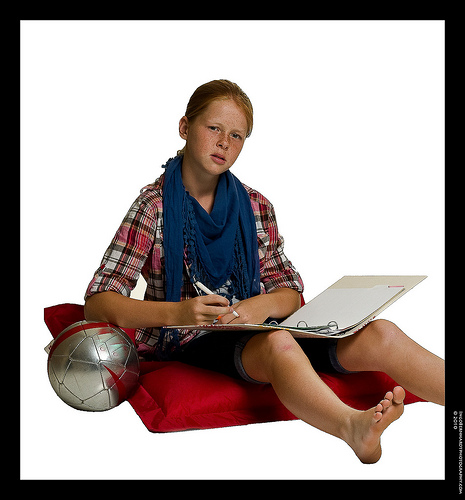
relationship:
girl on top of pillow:
[84, 79, 444, 462] [43, 302, 428, 431]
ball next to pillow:
[45, 321, 140, 411] [43, 302, 428, 431]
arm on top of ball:
[84, 196, 233, 323] [45, 321, 140, 411]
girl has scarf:
[84, 79, 444, 462] [150, 156, 258, 368]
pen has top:
[193, 280, 238, 320] [194, 281, 198, 282]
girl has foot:
[84, 79, 444, 462] [350, 386, 403, 464]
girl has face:
[84, 79, 444, 462] [201, 119, 243, 166]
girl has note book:
[84, 79, 444, 462] [162, 275, 426, 338]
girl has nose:
[84, 79, 444, 462] [217, 132, 229, 149]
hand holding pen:
[179, 294, 234, 326] [193, 280, 238, 320]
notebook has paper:
[162, 275, 426, 338] [277, 288, 401, 333]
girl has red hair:
[84, 79, 444, 462] [185, 80, 253, 137]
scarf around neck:
[150, 156, 258, 368] [181, 147, 220, 192]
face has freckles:
[201, 119, 243, 166] [191, 101, 244, 173]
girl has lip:
[84, 79, 444, 462] [203, 154, 230, 159]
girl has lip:
[84, 79, 444, 462] [212, 157, 226, 162]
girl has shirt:
[84, 79, 444, 462] [84, 174, 304, 359]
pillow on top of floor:
[43, 302, 428, 431] [19, 279, 444, 481]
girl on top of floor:
[84, 79, 444, 462] [19, 279, 444, 481]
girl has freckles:
[84, 79, 444, 462] [191, 101, 244, 173]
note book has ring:
[162, 275, 426, 338] [327, 321, 339, 329]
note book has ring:
[162, 275, 426, 338] [297, 321, 305, 328]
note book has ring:
[162, 275, 426, 338] [270, 321, 278, 326]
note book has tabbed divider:
[162, 275, 426, 338] [374, 284, 403, 289]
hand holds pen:
[179, 294, 234, 326] [193, 280, 238, 320]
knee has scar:
[266, 330, 297, 353] [282, 345, 293, 350]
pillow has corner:
[43, 302, 428, 431] [44, 303, 65, 324]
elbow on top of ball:
[82, 307, 94, 319] [45, 321, 140, 411]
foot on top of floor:
[350, 386, 403, 464] [19, 279, 444, 481]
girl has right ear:
[84, 79, 444, 462] [178, 117, 188, 141]